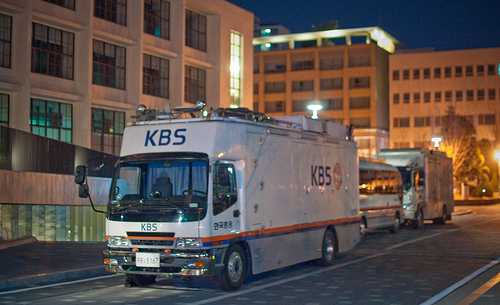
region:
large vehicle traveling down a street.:
[70, 88, 385, 291]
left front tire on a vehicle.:
[209, 240, 255, 291]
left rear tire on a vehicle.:
[307, 216, 348, 265]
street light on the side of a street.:
[292, 93, 335, 134]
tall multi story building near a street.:
[387, 42, 498, 225]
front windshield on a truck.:
[86, 133, 226, 233]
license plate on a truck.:
[126, 243, 169, 278]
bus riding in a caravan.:
[331, 153, 405, 237]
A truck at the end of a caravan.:
[364, 116, 454, 266]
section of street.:
[387, 236, 429, 301]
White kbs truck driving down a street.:
[58, 100, 374, 290]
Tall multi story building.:
[249, 21, 399, 164]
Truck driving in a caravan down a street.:
[361, 143, 468, 239]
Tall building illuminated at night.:
[379, 49, 494, 207]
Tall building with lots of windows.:
[0, 1, 257, 248]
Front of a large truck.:
[95, 140, 233, 239]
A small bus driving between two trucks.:
[325, 161, 406, 253]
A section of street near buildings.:
[365, 251, 460, 292]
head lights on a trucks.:
[95, 230, 212, 279]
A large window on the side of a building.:
[15, 93, 78, 160]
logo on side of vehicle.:
[305, 162, 345, 189]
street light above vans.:
[302, 99, 322, 112]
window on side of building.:
[95, 47, 123, 77]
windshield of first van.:
[117, 172, 199, 209]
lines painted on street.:
[454, 252, 490, 295]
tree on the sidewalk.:
[446, 117, 466, 167]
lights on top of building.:
[267, 28, 395, 45]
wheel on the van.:
[223, 252, 243, 277]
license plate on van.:
[130, 254, 164, 268]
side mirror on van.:
[75, 168, 100, 198]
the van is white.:
[92, 82, 377, 259]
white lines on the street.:
[191, 210, 480, 297]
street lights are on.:
[297, 90, 329, 123]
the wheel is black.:
[208, 223, 251, 283]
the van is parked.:
[75, 84, 412, 268]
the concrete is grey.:
[346, 207, 491, 287]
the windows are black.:
[383, 63, 490, 168]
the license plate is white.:
[124, 235, 174, 275]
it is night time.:
[229, 4, 479, 197]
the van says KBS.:
[127, 112, 212, 166]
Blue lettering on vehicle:
[138, 125, 201, 150]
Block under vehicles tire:
[111, 268, 144, 293]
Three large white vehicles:
[97, 98, 482, 277]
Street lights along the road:
[424, 112, 499, 177]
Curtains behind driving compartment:
[141, 160, 215, 200]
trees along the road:
[433, 102, 498, 216]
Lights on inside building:
[255, 17, 277, 56]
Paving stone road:
[32, 199, 497, 302]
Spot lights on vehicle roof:
[126, 99, 233, 124]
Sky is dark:
[258, 2, 499, 51]